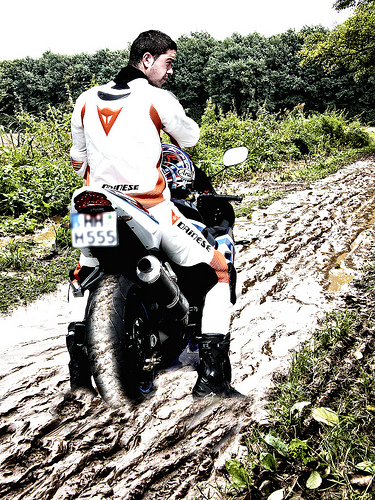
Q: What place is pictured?
A: It is a road.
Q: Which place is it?
A: It is a road.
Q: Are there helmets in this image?
A: Yes, there is a helmet.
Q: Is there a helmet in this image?
A: Yes, there is a helmet.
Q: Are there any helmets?
A: Yes, there is a helmet.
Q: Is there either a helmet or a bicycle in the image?
A: Yes, there is a helmet.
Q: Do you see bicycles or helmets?
A: Yes, there is a helmet.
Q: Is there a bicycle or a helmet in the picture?
A: Yes, there is a helmet.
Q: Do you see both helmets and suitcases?
A: No, there is a helmet but no suitcases.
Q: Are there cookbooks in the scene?
A: No, there are no cookbooks.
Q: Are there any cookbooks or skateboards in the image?
A: No, there are no cookbooks or skateboards.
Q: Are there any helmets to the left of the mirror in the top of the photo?
A: Yes, there is a helmet to the left of the mirror.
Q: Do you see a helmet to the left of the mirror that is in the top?
A: Yes, there is a helmet to the left of the mirror.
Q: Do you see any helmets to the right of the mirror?
A: No, the helmet is to the left of the mirror.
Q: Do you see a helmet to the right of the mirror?
A: No, the helmet is to the left of the mirror.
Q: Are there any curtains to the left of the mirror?
A: No, there is a helmet to the left of the mirror.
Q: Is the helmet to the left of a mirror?
A: Yes, the helmet is to the left of a mirror.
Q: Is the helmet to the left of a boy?
A: No, the helmet is to the left of a mirror.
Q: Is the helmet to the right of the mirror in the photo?
A: No, the helmet is to the left of the mirror.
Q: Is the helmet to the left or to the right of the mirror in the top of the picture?
A: The helmet is to the left of the mirror.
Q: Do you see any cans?
A: No, there are no cans.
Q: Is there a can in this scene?
A: No, there are no cans.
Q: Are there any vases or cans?
A: No, there are no cans or vases.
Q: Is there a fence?
A: No, there are no fences.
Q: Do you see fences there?
A: No, there are no fences.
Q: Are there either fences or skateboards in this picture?
A: No, there are no fences or skateboards.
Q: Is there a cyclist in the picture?
A: Yes, there is a cyclist.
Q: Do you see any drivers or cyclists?
A: Yes, there is a cyclist.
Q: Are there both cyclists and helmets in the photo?
A: Yes, there are both a cyclist and a helmet.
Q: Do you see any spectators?
A: No, there are no spectators.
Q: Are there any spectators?
A: No, there are no spectators.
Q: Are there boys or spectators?
A: No, there are no spectators or boys.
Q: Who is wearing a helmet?
A: The bicyclist is wearing a helmet.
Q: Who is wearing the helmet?
A: The bicyclist is wearing a helmet.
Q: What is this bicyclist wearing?
A: The bicyclist is wearing a helmet.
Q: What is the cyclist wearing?
A: The bicyclist is wearing a helmet.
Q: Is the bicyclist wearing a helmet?
A: Yes, the bicyclist is wearing a helmet.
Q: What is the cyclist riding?
A: The cyclist is riding a bike.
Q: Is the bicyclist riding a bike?
A: Yes, the bicyclist is riding a bike.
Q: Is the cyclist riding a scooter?
A: No, the cyclist is riding a bike.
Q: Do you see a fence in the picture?
A: No, there are no fences.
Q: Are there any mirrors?
A: Yes, there is a mirror.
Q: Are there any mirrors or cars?
A: Yes, there is a mirror.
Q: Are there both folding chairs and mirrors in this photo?
A: No, there is a mirror but no folding chairs.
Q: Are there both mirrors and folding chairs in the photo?
A: No, there is a mirror but no folding chairs.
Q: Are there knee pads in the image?
A: No, there are no knee pads.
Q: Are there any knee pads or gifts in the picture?
A: No, there are no knee pads or gifts.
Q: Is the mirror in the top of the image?
A: Yes, the mirror is in the top of the image.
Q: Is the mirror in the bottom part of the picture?
A: No, the mirror is in the top of the image.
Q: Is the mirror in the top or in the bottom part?
A: The mirror is in the top of the image.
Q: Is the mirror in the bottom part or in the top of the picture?
A: The mirror is in the top of the image.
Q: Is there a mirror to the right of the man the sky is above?
A: Yes, there is a mirror to the right of the man.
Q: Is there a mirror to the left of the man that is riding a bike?
A: No, the mirror is to the right of the man.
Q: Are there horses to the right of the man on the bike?
A: No, there is a mirror to the right of the man.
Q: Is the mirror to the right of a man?
A: Yes, the mirror is to the right of a man.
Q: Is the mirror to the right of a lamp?
A: No, the mirror is to the right of a man.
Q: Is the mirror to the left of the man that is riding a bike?
A: No, the mirror is to the right of the man.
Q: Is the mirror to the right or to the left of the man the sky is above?
A: The mirror is to the right of the man.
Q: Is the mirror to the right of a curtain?
A: No, the mirror is to the right of a man.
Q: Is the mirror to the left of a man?
A: No, the mirror is to the right of a man.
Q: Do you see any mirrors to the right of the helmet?
A: Yes, there is a mirror to the right of the helmet.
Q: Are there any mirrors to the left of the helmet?
A: No, the mirror is to the right of the helmet.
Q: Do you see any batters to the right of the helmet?
A: No, there is a mirror to the right of the helmet.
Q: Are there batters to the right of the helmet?
A: No, there is a mirror to the right of the helmet.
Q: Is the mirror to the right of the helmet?
A: Yes, the mirror is to the right of the helmet.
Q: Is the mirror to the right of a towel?
A: No, the mirror is to the right of the helmet.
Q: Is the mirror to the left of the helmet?
A: No, the mirror is to the right of the helmet.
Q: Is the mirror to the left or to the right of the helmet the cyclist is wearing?
A: The mirror is to the right of the helmet.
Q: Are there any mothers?
A: No, there are no mothers.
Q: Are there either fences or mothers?
A: No, there are no mothers or fences.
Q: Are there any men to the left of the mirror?
A: Yes, there is a man to the left of the mirror.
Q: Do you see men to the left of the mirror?
A: Yes, there is a man to the left of the mirror.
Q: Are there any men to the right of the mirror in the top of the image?
A: No, the man is to the left of the mirror.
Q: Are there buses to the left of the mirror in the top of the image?
A: No, there is a man to the left of the mirror.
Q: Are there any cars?
A: No, there are no cars.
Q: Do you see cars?
A: No, there are no cars.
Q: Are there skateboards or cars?
A: No, there are no cars or skateboards.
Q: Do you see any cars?
A: No, there are no cars.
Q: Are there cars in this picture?
A: No, there are no cars.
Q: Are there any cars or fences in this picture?
A: No, there are no cars or fences.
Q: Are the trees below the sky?
A: Yes, the trees are below the sky.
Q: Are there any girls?
A: No, there are no girls.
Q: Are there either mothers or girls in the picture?
A: No, there are no girls or mothers.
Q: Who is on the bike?
A: The man is on the bike.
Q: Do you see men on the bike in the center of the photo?
A: Yes, there is a man on the bike.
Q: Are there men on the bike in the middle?
A: Yes, there is a man on the bike.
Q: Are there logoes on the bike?
A: No, there is a man on the bike.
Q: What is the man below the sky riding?
A: The man is riding a bike.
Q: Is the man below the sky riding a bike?
A: Yes, the man is riding a bike.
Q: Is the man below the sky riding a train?
A: No, the man is riding a bike.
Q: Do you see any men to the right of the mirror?
A: No, the man is to the left of the mirror.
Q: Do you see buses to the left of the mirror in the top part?
A: No, there is a man to the left of the mirror.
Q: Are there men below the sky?
A: Yes, there is a man below the sky.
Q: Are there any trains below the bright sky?
A: No, there is a man below the sky.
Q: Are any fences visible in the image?
A: No, there are no fences.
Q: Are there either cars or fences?
A: No, there are no fences or cars.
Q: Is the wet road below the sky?
A: Yes, the road is below the sky.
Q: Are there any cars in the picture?
A: No, there are no cars.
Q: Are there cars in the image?
A: No, there are no cars.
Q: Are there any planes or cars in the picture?
A: No, there are no cars or planes.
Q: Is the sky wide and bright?
A: Yes, the sky is wide and bright.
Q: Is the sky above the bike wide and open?
A: Yes, the sky is wide and open.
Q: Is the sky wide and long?
A: Yes, the sky is wide and long.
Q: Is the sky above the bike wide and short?
A: No, the sky is wide but long.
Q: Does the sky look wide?
A: Yes, the sky is wide.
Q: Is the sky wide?
A: Yes, the sky is wide.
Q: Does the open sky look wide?
A: Yes, the sky is wide.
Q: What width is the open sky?
A: The sky is wide.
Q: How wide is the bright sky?
A: The sky is wide.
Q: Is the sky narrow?
A: No, the sky is wide.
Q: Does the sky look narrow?
A: No, the sky is wide.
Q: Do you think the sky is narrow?
A: No, the sky is wide.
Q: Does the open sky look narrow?
A: No, the sky is wide.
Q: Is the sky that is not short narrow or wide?
A: The sky is wide.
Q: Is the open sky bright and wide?
A: Yes, the sky is bright and wide.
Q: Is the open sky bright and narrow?
A: No, the sky is bright but wide.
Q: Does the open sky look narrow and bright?
A: No, the sky is bright but wide.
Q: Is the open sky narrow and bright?
A: No, the sky is bright but wide.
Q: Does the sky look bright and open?
A: Yes, the sky is bright and open.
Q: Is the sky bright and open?
A: Yes, the sky is bright and open.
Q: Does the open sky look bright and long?
A: Yes, the sky is bright and long.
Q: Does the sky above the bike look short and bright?
A: No, the sky is bright but long.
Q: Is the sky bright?
A: Yes, the sky is bright.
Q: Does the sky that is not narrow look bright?
A: Yes, the sky is bright.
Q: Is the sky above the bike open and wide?
A: Yes, the sky is open and wide.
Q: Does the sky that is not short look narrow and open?
A: No, the sky is open but wide.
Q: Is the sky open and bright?
A: Yes, the sky is open and bright.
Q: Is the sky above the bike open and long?
A: Yes, the sky is open and long.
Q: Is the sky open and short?
A: No, the sky is open but long.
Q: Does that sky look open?
A: Yes, the sky is open.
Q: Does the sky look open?
A: Yes, the sky is open.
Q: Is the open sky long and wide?
A: Yes, the sky is long and wide.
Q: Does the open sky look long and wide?
A: Yes, the sky is long and wide.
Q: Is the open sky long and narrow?
A: No, the sky is long but wide.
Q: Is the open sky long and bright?
A: Yes, the sky is long and bright.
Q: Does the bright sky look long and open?
A: Yes, the sky is long and open.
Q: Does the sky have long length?
A: Yes, the sky is long.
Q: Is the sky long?
A: Yes, the sky is long.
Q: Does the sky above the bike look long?
A: Yes, the sky is long.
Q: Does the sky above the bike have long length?
A: Yes, the sky is long.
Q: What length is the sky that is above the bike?
A: The sky is long.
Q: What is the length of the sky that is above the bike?
A: The sky is long.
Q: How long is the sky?
A: The sky is long.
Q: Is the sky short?
A: No, the sky is long.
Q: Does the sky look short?
A: No, the sky is long.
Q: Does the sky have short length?
A: No, the sky is long.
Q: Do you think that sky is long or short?
A: The sky is long.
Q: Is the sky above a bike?
A: Yes, the sky is above a bike.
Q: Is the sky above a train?
A: No, the sky is above a bike.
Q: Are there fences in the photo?
A: No, there are no fences.